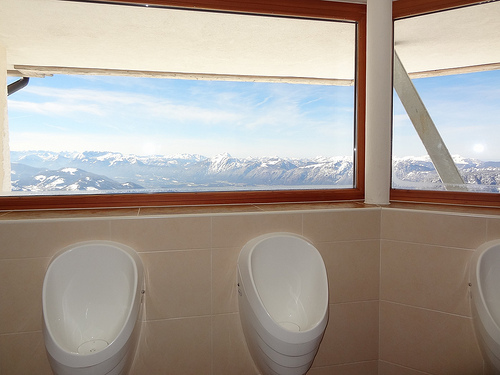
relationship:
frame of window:
[2, 3, 498, 210] [1, 3, 493, 185]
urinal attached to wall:
[40, 237, 140, 374] [13, 216, 498, 372]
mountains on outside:
[8, 149, 500, 193] [3, 66, 498, 191]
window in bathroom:
[1, 3, 493, 185] [3, 2, 499, 375]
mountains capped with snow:
[8, 149, 500, 193] [12, 139, 450, 170]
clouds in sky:
[20, 77, 330, 135] [9, 75, 497, 165]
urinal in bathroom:
[40, 237, 141, 373] [3, 2, 499, 375]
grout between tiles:
[10, 221, 484, 373] [13, 216, 498, 372]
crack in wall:
[205, 221, 222, 375] [13, 216, 498, 372]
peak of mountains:
[12, 139, 450, 170] [8, 149, 500, 193]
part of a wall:
[4, 217, 375, 371] [13, 216, 498, 372]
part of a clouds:
[13, 77, 197, 128] [20, 77, 330, 135]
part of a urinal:
[43, 334, 145, 372] [40, 237, 141, 373]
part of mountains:
[10, 146, 141, 193] [8, 149, 500, 193]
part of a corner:
[348, 2, 393, 191] [329, 0, 437, 207]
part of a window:
[4, 6, 360, 193] [1, 3, 493, 185]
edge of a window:
[2, 185, 355, 207] [1, 3, 493, 185]